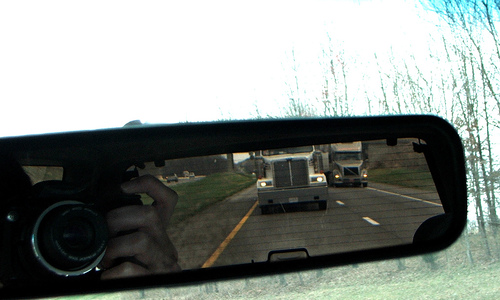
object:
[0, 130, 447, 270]
mirror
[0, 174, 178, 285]
person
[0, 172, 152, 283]
camera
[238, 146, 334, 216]
semi truck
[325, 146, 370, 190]
semi truck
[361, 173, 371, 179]
light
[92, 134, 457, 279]
reflection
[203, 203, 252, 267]
stripe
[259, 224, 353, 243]
road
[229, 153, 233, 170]
tree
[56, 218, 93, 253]
lens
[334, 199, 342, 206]
line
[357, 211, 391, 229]
line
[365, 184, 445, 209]
line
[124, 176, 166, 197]
finger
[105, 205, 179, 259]
finger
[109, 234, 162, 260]
finger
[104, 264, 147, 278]
finger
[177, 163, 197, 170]
tree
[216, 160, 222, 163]
background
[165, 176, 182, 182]
car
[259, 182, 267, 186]
headlights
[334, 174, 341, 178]
headlights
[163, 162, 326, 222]
street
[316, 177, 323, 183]
headlights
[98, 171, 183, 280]
hand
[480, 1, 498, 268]
trees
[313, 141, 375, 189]
trucks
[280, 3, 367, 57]
sun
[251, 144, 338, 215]
truck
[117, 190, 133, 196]
button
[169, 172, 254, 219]
grass